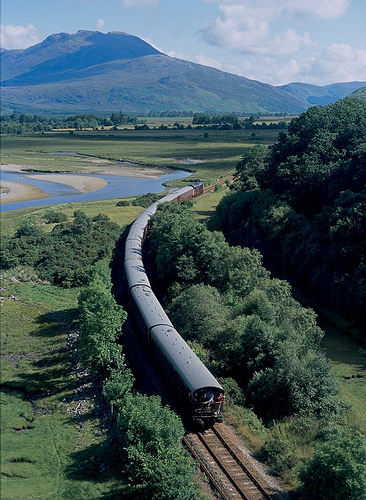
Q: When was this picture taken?
A: During the day.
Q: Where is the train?
A: On the train tracks.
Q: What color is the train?
A: Silver.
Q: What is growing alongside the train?
A: Trees.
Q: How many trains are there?
A: One.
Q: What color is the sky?
A: Blue.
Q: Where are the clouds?
A: In the sky.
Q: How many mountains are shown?
A: One.